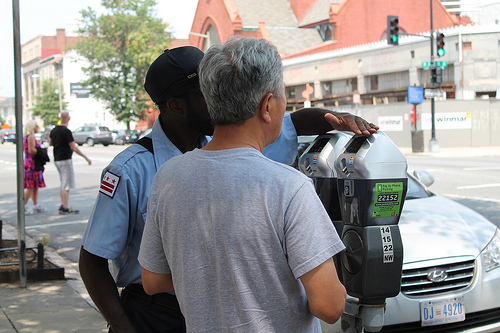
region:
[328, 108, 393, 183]
the man is holding his hand in front of the meter so they can read it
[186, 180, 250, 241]
the shirt is gray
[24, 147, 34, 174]
the dress is multi color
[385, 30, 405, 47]
the light is green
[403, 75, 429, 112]
the sign is blue and white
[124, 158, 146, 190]
the shirt is blue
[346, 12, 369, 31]
the roof is orange red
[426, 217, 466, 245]
the car is white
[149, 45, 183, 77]
the hat is black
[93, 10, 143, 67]
the tree has green leaves on it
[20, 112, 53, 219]
A woman in a pink, purple, and black dress.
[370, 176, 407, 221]
Green sticker on side of parking meter.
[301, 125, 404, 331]
Two chrome and grey parking meter.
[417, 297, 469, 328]
White license plate with blue letters and numbers.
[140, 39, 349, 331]
Man wearing grey shirt.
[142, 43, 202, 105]
Dark baseball cap worn by man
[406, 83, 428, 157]
Blue sign on pole and stone pillar.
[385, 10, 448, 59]
Two traffic lights showing green lights.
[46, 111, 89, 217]
Man in a black top and light colored shorts.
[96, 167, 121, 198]
White shirt patch with red lines and red stars.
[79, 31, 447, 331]
people looking at parking meter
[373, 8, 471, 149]
green lights on pole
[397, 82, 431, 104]
blue and white sign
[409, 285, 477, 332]
blue and white license plate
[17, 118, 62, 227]
lady wearing pink dress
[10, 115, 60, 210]
lady carrying black sweater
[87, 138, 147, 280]
red and white patch on shirt sleeve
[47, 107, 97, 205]
guy wearing black shirt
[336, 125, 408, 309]
green label on parking meter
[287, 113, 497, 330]
car parked next to parking meter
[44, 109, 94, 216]
man with black shirt and gray shorts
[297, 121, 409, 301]
black and silver parking meters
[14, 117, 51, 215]
blond woman with pink and black dress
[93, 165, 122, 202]
black white and red insignia patch on a shirtsleeve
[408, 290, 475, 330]
blue and white license plate on a car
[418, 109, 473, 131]
advertising sign on a wall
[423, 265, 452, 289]
oval gray and silver insignia on a car grill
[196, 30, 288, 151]
man's head with short gray hair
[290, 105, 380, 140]
man's arm touching a parking meter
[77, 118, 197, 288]
blue shirt with a black strap over the shoulder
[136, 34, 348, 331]
man in gray shirt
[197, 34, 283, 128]
man has gray hair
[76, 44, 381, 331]
parking meter attendant is helping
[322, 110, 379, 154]
hand shading meter screen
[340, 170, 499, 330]
license plate on parked sedan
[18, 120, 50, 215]
woman in colorful dress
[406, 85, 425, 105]
street sign is royal blue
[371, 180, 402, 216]
sticker on meter is green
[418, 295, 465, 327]
license plate is rectangle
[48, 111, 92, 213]
man wearing black shirt